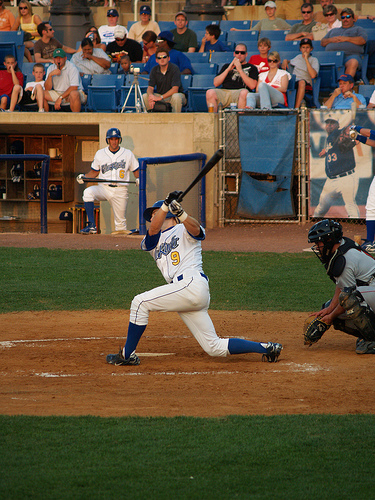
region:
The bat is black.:
[163, 138, 229, 226]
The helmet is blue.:
[140, 182, 182, 224]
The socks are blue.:
[102, 310, 290, 380]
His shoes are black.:
[103, 348, 292, 376]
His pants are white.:
[98, 274, 243, 364]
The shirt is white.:
[140, 219, 209, 281]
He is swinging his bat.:
[97, 146, 287, 401]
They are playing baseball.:
[23, 139, 371, 456]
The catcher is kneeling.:
[285, 203, 372, 374]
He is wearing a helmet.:
[301, 213, 339, 256]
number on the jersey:
[167, 245, 182, 272]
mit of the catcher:
[285, 310, 332, 352]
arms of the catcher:
[343, 285, 364, 344]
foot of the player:
[100, 345, 138, 367]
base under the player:
[116, 341, 176, 364]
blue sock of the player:
[217, 333, 264, 363]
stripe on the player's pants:
[122, 278, 188, 324]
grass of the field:
[6, 397, 361, 484]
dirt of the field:
[0, 300, 308, 435]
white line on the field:
[9, 349, 310, 414]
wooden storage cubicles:
[2, 132, 73, 202]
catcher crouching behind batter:
[301, 216, 374, 354]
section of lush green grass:
[0, 411, 374, 499]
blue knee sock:
[226, 336, 265, 359]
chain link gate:
[216, 100, 309, 228]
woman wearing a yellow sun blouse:
[10, 1, 44, 63]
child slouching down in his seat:
[5, 59, 45, 112]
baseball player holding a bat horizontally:
[75, 126, 139, 234]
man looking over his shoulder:
[31, 19, 78, 65]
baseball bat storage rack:
[68, 204, 100, 234]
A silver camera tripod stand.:
[118, 79, 149, 113]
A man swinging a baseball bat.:
[104, 142, 283, 365]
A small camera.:
[128, 65, 140, 73]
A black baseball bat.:
[169, 148, 227, 210]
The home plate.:
[120, 348, 176, 358]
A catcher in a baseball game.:
[297, 219, 372, 359]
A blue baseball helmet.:
[104, 126, 123, 144]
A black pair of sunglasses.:
[232, 50, 244, 55]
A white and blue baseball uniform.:
[119, 219, 272, 369]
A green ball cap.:
[52, 48, 65, 59]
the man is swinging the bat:
[148, 157, 226, 266]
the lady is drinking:
[82, 24, 101, 44]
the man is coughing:
[77, 37, 104, 66]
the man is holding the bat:
[87, 126, 137, 209]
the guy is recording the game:
[124, 50, 178, 90]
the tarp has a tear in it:
[242, 151, 287, 196]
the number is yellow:
[165, 246, 182, 263]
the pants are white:
[169, 287, 192, 299]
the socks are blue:
[225, 327, 259, 351]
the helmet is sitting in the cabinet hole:
[46, 180, 62, 198]